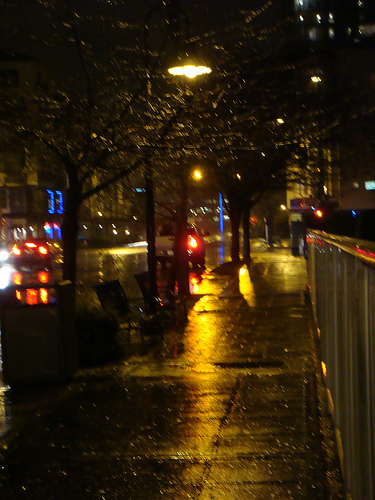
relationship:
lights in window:
[37, 171, 74, 230] [23, 154, 104, 261]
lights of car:
[176, 235, 214, 284] [128, 204, 230, 302]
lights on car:
[176, 235, 214, 284] [95, 197, 240, 304]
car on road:
[136, 213, 236, 285] [28, 216, 319, 455]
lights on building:
[37, 171, 74, 230] [3, 80, 233, 300]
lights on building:
[24, 157, 121, 279] [18, 91, 215, 310]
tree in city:
[74, 8, 177, 325] [0, 0, 373, 488]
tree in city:
[197, 3, 308, 266] [0, 0, 373, 488]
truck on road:
[150, 218, 205, 271] [114, 232, 221, 275]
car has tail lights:
[7, 236, 61, 268] [7, 240, 50, 254]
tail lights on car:
[7, 241, 46, 257] [3, 258, 68, 293]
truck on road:
[3, 226, 71, 266] [32, 228, 255, 395]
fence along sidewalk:
[301, 224, 373, 500] [43, 253, 339, 500]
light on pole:
[191, 167, 203, 182] [168, 173, 189, 314]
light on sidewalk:
[191, 167, 203, 182] [43, 253, 339, 500]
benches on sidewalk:
[89, 264, 163, 323] [32, 251, 335, 469]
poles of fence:
[136, 171, 164, 303] [296, 271, 370, 460]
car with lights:
[7, 236, 61, 268] [37, 246, 50, 254]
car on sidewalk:
[7, 236, 61, 268] [32, 251, 335, 469]